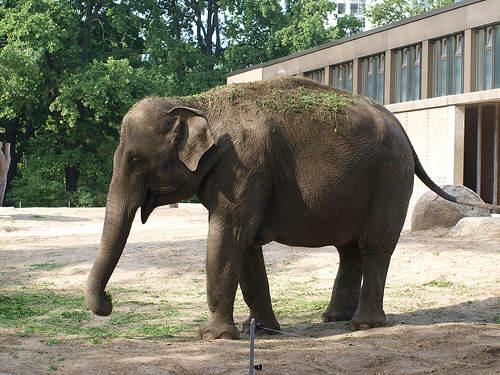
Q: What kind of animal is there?
A: An elephant.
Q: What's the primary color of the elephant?
A: Gray.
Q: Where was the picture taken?
A: In a zoo.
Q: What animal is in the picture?
A: Elephant.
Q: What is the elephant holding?
A: Grass.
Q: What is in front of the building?
A: Boulders.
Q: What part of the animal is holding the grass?
A: Trunk.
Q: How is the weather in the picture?
A: Sunny.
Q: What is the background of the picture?
A: Trees.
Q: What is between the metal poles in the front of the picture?
A: Wire.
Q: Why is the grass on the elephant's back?
A: For sun protection.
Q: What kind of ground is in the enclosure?
A: Dirt.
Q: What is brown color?
A: Building.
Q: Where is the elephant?
A: On dirt.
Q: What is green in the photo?
A: Tree leaves.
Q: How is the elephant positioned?
A: Standing.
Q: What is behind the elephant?
A: Building.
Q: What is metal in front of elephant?
A: Wire fence.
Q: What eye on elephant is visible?
A: Left eye.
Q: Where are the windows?
A: On building.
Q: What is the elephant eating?
A: Grass.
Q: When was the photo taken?
A: In the daytime.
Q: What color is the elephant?
A: Dark grey.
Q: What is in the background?
A: A building.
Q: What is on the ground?
A: Sand.